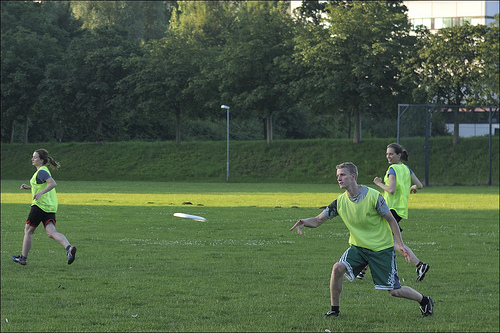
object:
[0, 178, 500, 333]
grass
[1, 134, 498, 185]
bushes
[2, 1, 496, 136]
trees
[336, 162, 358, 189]
head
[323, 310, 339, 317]
foot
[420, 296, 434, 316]
foot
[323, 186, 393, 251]
shirt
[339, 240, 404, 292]
shorts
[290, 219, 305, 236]
right hand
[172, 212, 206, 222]
frisbee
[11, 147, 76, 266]
girl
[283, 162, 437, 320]
people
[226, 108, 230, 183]
pole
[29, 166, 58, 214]
shirt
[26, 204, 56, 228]
shorts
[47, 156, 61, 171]
pony tail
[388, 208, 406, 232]
shoes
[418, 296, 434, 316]
shoes